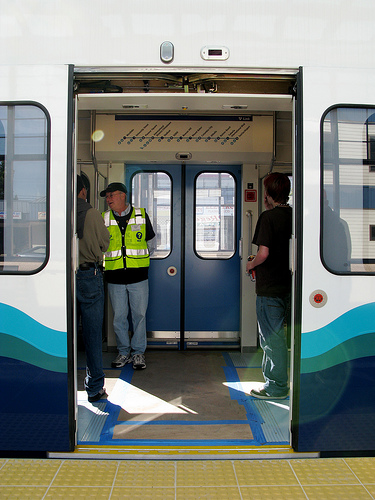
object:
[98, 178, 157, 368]
man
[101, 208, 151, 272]
vest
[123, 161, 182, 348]
door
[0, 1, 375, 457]
train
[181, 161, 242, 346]
door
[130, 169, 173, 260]
window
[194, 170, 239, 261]
window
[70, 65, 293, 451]
doorway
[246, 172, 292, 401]
man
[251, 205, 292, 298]
shirt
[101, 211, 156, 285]
shirt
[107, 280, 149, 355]
jeans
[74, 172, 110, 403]
man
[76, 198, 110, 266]
shirt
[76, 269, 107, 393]
jeans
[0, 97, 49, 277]
window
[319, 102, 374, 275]
window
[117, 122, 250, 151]
guide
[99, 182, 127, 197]
cap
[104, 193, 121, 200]
glasses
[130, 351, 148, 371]
shoe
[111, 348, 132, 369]
shoe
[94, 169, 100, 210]
grab bar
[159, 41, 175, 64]
light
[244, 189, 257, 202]
alarm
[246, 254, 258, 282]
drink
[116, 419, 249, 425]
line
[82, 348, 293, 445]
floor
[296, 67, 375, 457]
door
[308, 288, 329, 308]
handle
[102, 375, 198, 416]
light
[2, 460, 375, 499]
platform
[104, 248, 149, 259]
line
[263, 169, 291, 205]
hair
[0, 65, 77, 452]
door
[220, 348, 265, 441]
line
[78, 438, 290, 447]
line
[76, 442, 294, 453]
doorstep